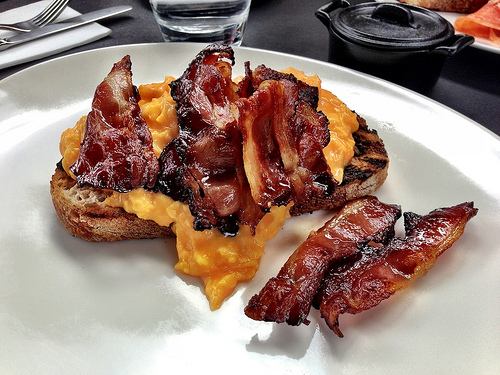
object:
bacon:
[97, 67, 331, 206]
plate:
[0, 40, 500, 374]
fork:
[0, 0, 70, 33]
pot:
[314, 0, 474, 90]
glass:
[150, 0, 252, 47]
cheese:
[172, 200, 265, 310]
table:
[0, 0, 500, 134]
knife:
[0, 5, 132, 52]